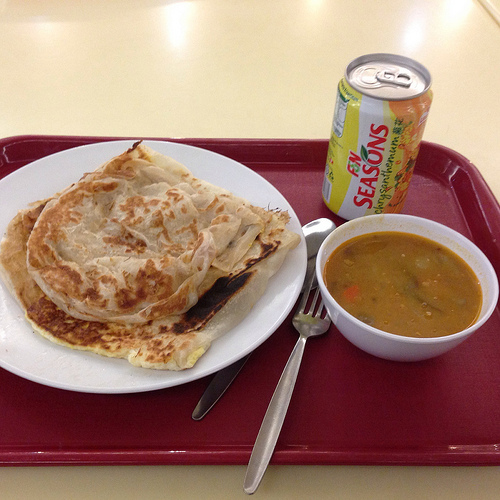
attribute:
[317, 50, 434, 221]
drink — closed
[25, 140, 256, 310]
pancake —  brown and white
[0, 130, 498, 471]
tray — red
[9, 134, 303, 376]
bread — naan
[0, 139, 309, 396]
plate — white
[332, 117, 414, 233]
leter — red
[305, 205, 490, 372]
bowl — white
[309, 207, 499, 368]
pot — white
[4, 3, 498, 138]
wall —  light brown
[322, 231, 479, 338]
soup — indian,  brown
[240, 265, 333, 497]
fork — silver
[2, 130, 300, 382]
pancake — burnt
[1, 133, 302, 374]
item — bready